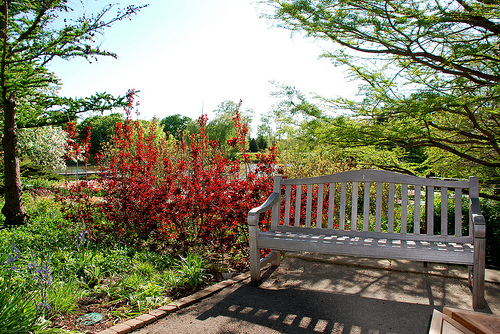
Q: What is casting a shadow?
A: Bench.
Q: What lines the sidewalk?
A: Bricks.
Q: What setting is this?
A: Garden.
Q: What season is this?
A: Spring.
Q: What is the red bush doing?
A: Blooming.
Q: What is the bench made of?
A: Wood.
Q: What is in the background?
A: Pond.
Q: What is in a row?
A: Bricks.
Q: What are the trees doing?
A: Budding.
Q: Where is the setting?
A: In a park.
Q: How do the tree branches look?
A: They are long.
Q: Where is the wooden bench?
A: At a park.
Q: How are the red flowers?
A: They are in a bush.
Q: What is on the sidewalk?
A: The shadow of the bench.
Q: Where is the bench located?
A: In the middle of the park.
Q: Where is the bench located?
A: The bench is near some trees.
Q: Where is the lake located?
A: Behind the flowers.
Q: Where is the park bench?
A: Next to the red bush.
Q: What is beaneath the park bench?
A: A shadow.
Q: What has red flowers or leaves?
A: Tall plants.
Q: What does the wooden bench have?
A: A shadow.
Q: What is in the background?
A: Many far away trees.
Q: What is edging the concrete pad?
A: The brick.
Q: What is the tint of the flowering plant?
A: Red.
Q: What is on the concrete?
A: The shadow of a bench.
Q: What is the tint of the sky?
A: Pale blue.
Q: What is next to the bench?
A: Tree branches.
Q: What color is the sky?
A: Blue.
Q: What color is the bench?
A: Gray.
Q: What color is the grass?
A: Green.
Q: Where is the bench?
A: On the dirt.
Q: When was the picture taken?
A: Daytime.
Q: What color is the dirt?
A: Brown.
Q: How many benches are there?
A: One.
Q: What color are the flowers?
A: Red.